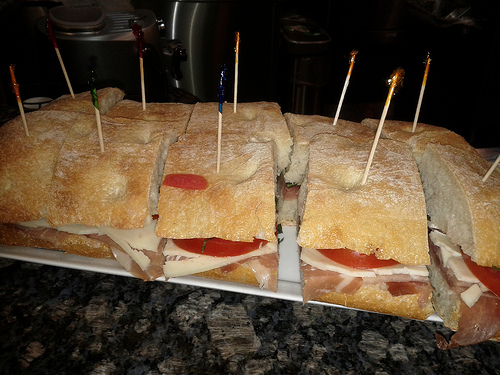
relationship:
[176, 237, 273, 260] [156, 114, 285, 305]
tomato in sub sandwich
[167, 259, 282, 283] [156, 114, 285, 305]
meat inside sub sandwich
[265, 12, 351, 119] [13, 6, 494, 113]
side table in background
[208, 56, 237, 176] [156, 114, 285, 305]
toothpick in sub sandwich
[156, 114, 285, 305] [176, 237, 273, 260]
sub sandwich has tomato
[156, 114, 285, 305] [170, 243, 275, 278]
sub sandwich has cheese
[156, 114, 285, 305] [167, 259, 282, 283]
sub sandwich has meat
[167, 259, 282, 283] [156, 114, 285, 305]
meat in sub sandwich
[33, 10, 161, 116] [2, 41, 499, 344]
two red toothpicks are in sandwich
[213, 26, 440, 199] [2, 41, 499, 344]
orange toothpicks are in sandwich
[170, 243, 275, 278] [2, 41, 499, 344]
cheese on sandwich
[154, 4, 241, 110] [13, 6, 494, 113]
drink dispenser in background